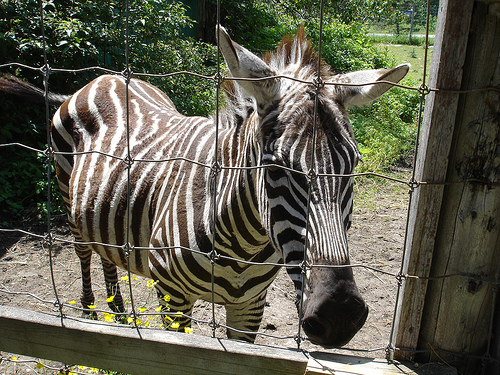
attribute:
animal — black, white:
[42, 20, 415, 348]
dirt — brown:
[6, 198, 408, 350]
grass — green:
[389, 43, 438, 83]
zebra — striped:
[21, 10, 414, 373]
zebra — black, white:
[18, 47, 417, 355]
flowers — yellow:
[10, 234, 256, 372]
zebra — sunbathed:
[25, 36, 443, 371]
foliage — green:
[163, 16, 427, 61]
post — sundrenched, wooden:
[22, 277, 454, 370]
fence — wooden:
[2, 3, 498, 370]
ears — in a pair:
[172, 15, 450, 139]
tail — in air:
[0, 55, 115, 153]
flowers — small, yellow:
[29, 250, 234, 373]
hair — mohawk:
[200, 19, 385, 104]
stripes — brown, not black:
[75, 65, 297, 246]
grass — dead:
[14, 160, 390, 357]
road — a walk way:
[356, 18, 453, 53]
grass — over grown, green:
[315, 21, 435, 73]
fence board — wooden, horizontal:
[6, 273, 332, 373]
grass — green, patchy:
[282, 167, 446, 209]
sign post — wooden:
[388, 0, 439, 67]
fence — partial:
[25, 245, 412, 370]